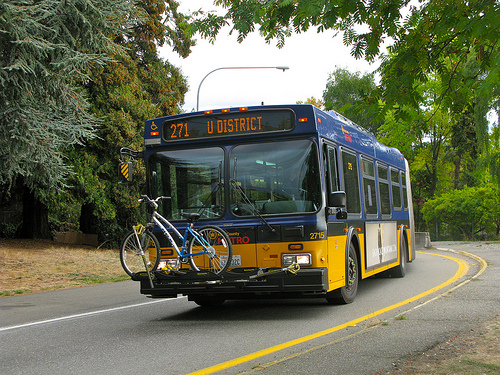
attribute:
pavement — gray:
[111, 342, 160, 358]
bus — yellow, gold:
[235, 125, 424, 291]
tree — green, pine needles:
[67, 209, 95, 237]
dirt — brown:
[23, 258, 68, 276]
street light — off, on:
[196, 55, 285, 103]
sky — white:
[305, 41, 324, 51]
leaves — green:
[131, 53, 175, 74]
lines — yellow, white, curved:
[244, 344, 285, 359]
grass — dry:
[95, 275, 114, 283]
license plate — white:
[215, 249, 245, 270]